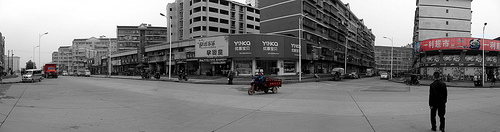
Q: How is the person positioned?
A: Upright.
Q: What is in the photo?
A: Buildings.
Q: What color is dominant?
A: Gray.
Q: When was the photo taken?
A: Daytime.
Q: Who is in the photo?
A: A man.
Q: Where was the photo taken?
A: On a city street.